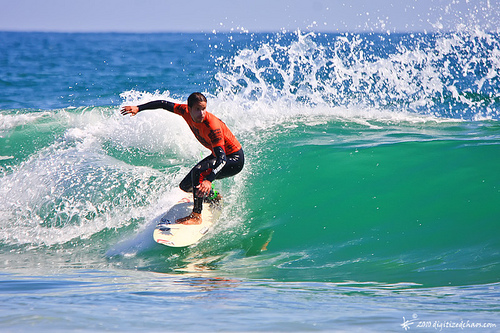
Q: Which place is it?
A: It is a sea.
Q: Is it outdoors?
A: Yes, it is outdoors.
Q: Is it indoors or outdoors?
A: It is outdoors.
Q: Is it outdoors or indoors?
A: It is outdoors.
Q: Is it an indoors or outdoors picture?
A: It is outdoors.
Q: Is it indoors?
A: No, it is outdoors.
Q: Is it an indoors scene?
A: No, it is outdoors.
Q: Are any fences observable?
A: No, there are no fences.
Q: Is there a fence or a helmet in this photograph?
A: No, there are no fences or helmets.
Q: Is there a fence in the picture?
A: No, there are no fences.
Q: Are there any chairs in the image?
A: No, there are no chairs.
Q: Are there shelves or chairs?
A: No, there are no chairs or shelves.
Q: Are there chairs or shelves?
A: No, there are no chairs or shelves.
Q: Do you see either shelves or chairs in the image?
A: No, there are no chairs or shelves.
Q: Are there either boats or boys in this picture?
A: No, there are no boys or boats.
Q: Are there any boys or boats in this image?
A: No, there are no boys or boats.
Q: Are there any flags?
A: No, there are no flags.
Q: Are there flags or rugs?
A: No, there are no flags or rugs.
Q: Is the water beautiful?
A: Yes, the water is beautiful.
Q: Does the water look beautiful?
A: Yes, the water is beautiful.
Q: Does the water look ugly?
A: No, the water is beautiful.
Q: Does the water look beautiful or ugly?
A: The water is beautiful.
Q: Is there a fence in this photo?
A: No, there are no fences.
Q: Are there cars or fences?
A: No, there are no fences or cars.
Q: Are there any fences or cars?
A: No, there are no fences or cars.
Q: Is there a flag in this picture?
A: No, there are no flags.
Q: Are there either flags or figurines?
A: No, there are no flags or figurines.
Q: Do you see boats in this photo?
A: No, there are no boats.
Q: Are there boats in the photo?
A: No, there are no boats.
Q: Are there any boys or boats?
A: No, there are no boats or boys.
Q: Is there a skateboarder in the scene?
A: No, there are no skateboarders.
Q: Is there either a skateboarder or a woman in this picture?
A: No, there are no skateboarders or women.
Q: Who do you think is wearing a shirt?
A: The man is wearing a shirt.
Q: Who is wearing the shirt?
A: The man is wearing a shirt.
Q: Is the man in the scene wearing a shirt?
A: Yes, the man is wearing a shirt.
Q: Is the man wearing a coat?
A: No, the man is wearing a shirt.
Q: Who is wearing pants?
A: The man is wearing pants.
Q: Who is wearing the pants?
A: The man is wearing pants.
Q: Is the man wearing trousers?
A: Yes, the man is wearing trousers.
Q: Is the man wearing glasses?
A: No, the man is wearing trousers.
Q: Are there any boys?
A: No, there are no boys.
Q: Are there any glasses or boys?
A: No, there are no boys or glasses.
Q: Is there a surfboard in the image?
A: Yes, there is a surfboard.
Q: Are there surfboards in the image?
A: Yes, there is a surfboard.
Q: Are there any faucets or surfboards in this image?
A: Yes, there is a surfboard.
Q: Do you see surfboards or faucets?
A: Yes, there is a surfboard.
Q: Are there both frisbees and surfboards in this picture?
A: No, there is a surfboard but no frisbees.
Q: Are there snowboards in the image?
A: No, there are no snowboards.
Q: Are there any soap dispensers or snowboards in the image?
A: No, there are no snowboards or soap dispensers.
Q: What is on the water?
A: The surf board is on the water.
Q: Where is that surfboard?
A: The surfboard is on the water.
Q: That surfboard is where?
A: The surfboard is on the water.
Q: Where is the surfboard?
A: The surfboard is on the water.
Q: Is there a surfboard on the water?
A: Yes, there is a surfboard on the water.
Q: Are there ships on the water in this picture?
A: No, there is a surfboard on the water.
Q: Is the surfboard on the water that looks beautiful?
A: Yes, the surfboard is on the water.